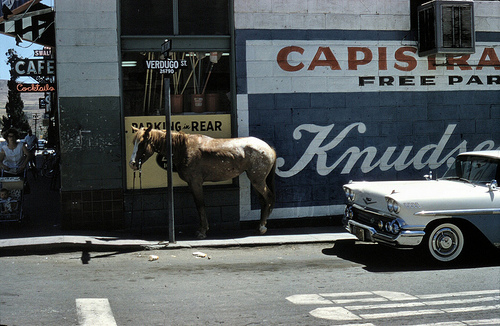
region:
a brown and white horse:
[126, 120, 276, 235]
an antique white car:
[339, 148, 499, 265]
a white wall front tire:
[424, 219, 469, 266]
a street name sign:
[138, 57, 190, 69]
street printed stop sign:
[285, 279, 497, 324]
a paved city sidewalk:
[1, 211, 364, 245]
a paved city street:
[1, 243, 498, 323]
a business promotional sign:
[9, 57, 55, 94]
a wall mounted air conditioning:
[415, 0, 475, 59]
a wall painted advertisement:
[235, 28, 496, 222]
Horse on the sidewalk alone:
[60, 26, 493, 296]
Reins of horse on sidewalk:
[93, 134, 160, 226]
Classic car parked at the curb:
[341, 138, 495, 254]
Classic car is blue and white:
[362, 161, 498, 274]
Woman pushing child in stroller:
[0, 106, 52, 218]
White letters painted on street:
[287, 274, 497, 322]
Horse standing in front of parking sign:
[96, 109, 243, 204]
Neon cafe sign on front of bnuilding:
[4, 39, 64, 101]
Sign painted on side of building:
[225, 32, 493, 237]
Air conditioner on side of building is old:
[403, 0, 487, 62]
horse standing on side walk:
[132, 114, 306, 229]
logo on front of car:
[361, 188, 381, 216]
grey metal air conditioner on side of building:
[412, 0, 489, 61]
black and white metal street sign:
[136, 50, 192, 76]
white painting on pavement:
[281, 274, 498, 324]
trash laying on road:
[120, 243, 223, 268]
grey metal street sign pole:
[152, 33, 185, 238]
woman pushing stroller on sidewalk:
[0, 130, 34, 224]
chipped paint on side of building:
[60, 112, 121, 154]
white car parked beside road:
[324, 150, 498, 261]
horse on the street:
[120, 115, 284, 245]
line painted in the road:
[70, 290, 123, 324]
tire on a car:
[420, 213, 474, 265]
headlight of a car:
[382, 193, 407, 214]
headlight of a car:
[342, 185, 357, 203]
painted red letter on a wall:
[272, 42, 309, 77]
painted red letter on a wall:
[301, 39, 347, 77]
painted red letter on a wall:
[340, 39, 376, 81]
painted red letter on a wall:
[370, 43, 389, 73]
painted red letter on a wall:
[390, 40, 424, 72]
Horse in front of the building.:
[120, 117, 285, 242]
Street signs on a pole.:
[142, 35, 199, 79]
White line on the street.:
[66, 282, 127, 322]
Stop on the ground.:
[286, 286, 498, 324]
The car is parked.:
[339, 134, 499, 269]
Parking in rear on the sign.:
[126, 118, 248, 140]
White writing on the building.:
[278, 106, 497, 202]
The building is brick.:
[241, 13, 497, 187]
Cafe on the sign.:
[6, 50, 53, 91]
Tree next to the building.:
[3, 51, 45, 172]